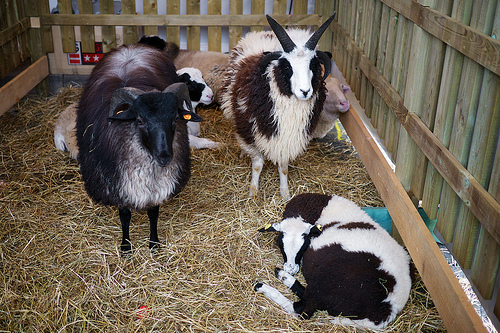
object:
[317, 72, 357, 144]
sheep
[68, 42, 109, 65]
sign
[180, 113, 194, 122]
tag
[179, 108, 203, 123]
ear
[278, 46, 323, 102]
face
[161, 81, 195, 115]
horns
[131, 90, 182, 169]
face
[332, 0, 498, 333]
rail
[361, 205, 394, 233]
fabric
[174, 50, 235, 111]
sheep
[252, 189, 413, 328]
goat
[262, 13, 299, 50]
horn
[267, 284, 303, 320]
leg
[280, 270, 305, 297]
leg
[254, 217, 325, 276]
head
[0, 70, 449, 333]
ground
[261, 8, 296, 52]
horn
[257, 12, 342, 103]
goat's head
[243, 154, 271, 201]
leg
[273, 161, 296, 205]
leg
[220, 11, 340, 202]
goat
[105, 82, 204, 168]
head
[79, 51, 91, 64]
star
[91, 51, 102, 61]
star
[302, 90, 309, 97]
nose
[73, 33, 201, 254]
ram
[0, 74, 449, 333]
hay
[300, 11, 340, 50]
horn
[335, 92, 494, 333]
wall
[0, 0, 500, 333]
stall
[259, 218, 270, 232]
tag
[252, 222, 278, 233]
sheep's ear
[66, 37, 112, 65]
sticker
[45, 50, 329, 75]
wall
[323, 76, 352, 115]
sheep's head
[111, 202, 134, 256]
legs